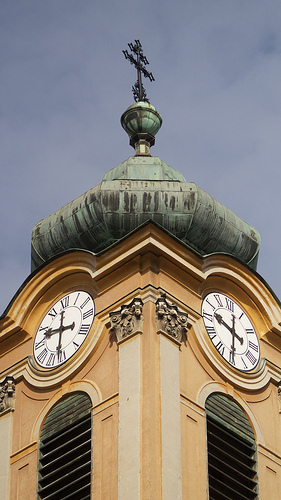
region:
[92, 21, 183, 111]
a weather vane on top of the building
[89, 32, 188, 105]
the weather vane is black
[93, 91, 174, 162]
a ball under the weather vane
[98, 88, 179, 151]
the ball is green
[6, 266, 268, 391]
two clocks on the building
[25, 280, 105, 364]
the clock face is white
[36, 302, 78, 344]
the hands on the clock are black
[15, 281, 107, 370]
the numbers are roman numerals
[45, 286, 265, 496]
the building is tan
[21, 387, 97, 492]
the windows have slats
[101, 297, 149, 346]
some decorative designs on a building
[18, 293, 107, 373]
a clock face on the side of a building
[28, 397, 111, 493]
a window with air vents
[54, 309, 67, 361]
the minute hand on a clock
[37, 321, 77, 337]
the hour hand on a clock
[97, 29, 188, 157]
a cross at the top of a building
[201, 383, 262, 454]
wooden slats near the top of a window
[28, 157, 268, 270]
a structure near the top of a building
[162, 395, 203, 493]
the side of a tall building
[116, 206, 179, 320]
the corner of a tall building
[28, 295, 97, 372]
black and white clock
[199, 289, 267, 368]
black and white clock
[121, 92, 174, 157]
green steeple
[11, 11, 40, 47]
white clouds in blue sky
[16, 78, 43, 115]
white clouds in blue sky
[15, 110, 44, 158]
white clouds in blue sky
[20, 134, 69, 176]
white clouds in blue sky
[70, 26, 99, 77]
white clouds in blue sky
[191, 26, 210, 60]
white clouds in blue sky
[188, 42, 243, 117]
white clouds in blue sky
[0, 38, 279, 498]
a tower with clocks on the sides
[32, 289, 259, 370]
two white face Roman numeral clocks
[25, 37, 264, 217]
the top of a clock tower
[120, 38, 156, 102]
the tip of the clock tower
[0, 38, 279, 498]
a historical clock tower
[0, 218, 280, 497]
two sides of a clock tower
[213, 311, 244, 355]
the hour and minute hands on a white face clock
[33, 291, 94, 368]
Roman numerals on the clock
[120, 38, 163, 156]
a cross on top of a clock tower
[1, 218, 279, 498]
a beige clock tower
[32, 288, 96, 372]
round clock on left side of tower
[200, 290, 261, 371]
round clock on right side of tower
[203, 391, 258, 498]
velour window on right side of tower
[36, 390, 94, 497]
velour window on left side of tower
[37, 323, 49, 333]
Roman numeral 10 on left clock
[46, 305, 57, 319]
roman numeral 11 on left clock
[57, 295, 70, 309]
roman numeral 12 on left side clock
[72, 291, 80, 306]
roman numeral one on left side of clock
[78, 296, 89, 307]
roman numeral 2 on left side clock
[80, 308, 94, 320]
roman numeral 3 on left side clock